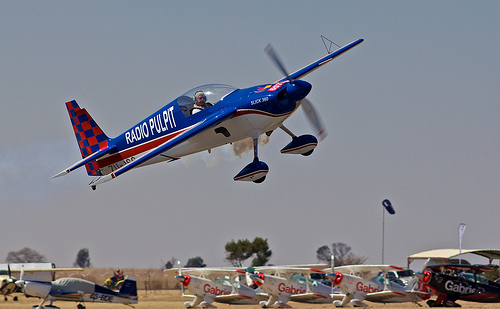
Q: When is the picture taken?
A: Daytime.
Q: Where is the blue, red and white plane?
A: In the air.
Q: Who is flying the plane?
A: Person under the cowling.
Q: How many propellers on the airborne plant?
A: One.